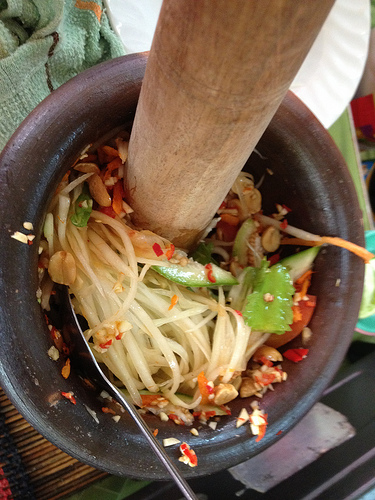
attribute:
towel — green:
[0, 0, 116, 132]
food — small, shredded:
[54, 153, 299, 436]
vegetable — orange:
[69, 150, 138, 231]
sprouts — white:
[27, 200, 292, 401]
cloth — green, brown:
[0, 2, 123, 156]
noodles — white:
[68, 210, 241, 387]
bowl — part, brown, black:
[3, 49, 368, 476]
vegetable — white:
[59, 198, 269, 408]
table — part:
[311, 442, 320, 462]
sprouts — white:
[70, 194, 368, 408]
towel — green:
[22, 18, 76, 62]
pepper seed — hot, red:
[85, 155, 130, 204]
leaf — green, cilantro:
[222, 245, 313, 347]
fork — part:
[52, 289, 260, 495]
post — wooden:
[122, 0, 335, 250]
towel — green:
[1, 9, 103, 140]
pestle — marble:
[125, 1, 352, 253]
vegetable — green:
[175, 242, 304, 332]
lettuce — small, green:
[173, 251, 232, 295]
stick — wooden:
[123, 0, 336, 255]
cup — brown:
[2, 97, 368, 414]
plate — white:
[288, 2, 372, 131]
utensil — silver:
[62, 286, 197, 499]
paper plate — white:
[106, 2, 372, 128]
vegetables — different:
[102, 230, 250, 311]